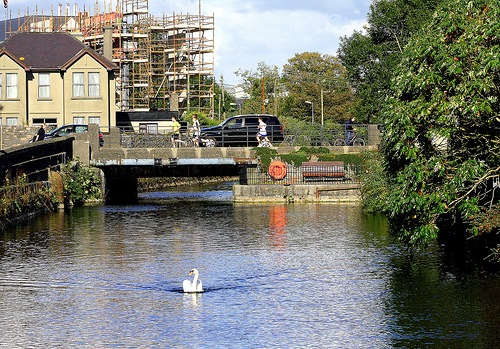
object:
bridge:
[73, 124, 380, 203]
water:
[0, 201, 499, 349]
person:
[256, 117, 274, 147]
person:
[344, 117, 357, 146]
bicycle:
[174, 133, 216, 147]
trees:
[377, 0, 500, 249]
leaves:
[386, 59, 481, 115]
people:
[192, 118, 200, 149]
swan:
[183, 268, 205, 292]